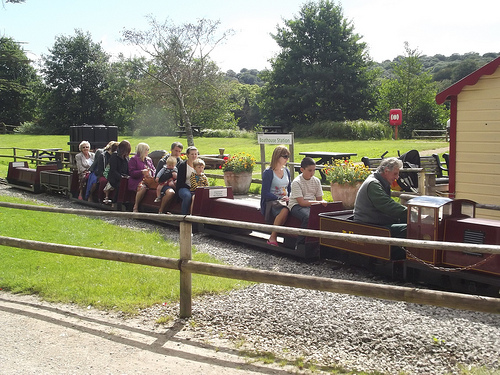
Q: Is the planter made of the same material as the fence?
A: No, the planter is made of concrete and the fence is made of wood.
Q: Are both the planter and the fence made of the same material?
A: No, the planter is made of concrete and the fence is made of wood.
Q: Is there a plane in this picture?
A: No, there are no airplanes.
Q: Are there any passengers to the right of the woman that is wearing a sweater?
A: Yes, there are passengers to the right of the woman.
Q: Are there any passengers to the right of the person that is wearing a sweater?
A: Yes, there are passengers to the right of the woman.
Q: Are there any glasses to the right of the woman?
A: No, there are passengers to the right of the woman.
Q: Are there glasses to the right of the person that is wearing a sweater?
A: No, there are passengers to the right of the woman.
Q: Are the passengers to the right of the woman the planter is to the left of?
A: Yes, the passengers are to the right of the woman.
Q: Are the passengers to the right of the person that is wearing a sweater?
A: Yes, the passengers are to the right of the woman.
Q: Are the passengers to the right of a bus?
A: No, the passengers are to the right of the woman.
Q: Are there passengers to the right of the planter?
A: Yes, there are passengers to the right of the planter.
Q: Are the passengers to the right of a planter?
A: Yes, the passengers are to the right of a planter.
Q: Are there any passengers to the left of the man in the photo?
A: Yes, there are passengers to the left of the man.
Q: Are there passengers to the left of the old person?
A: Yes, there are passengers to the left of the man.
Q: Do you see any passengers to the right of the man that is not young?
A: No, the passengers are to the left of the man.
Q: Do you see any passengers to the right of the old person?
A: No, the passengers are to the left of the man.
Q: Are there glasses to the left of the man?
A: No, there are passengers to the left of the man.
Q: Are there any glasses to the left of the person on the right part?
A: No, there are passengers to the left of the man.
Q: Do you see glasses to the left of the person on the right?
A: No, there are passengers to the left of the man.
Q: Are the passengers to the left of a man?
A: Yes, the passengers are to the left of a man.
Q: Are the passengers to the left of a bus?
A: No, the passengers are to the left of a man.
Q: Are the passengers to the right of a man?
A: No, the passengers are to the left of a man.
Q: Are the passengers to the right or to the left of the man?
A: The passengers are to the left of the man.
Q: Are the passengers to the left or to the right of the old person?
A: The passengers are to the left of the man.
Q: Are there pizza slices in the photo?
A: No, there are no pizza slices.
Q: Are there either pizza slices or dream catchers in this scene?
A: No, there are no pizza slices or dream catchers.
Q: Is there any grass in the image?
A: Yes, there is grass.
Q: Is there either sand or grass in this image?
A: Yes, there is grass.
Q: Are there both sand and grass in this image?
A: No, there is grass but no sand.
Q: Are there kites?
A: No, there are no kites.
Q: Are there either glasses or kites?
A: No, there are no kites or glasses.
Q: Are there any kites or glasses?
A: No, there are no kites or glasses.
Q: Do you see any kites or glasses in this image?
A: No, there are no kites or glasses.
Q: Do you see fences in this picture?
A: Yes, there is a fence.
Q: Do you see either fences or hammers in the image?
A: Yes, there is a fence.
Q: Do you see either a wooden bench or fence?
A: Yes, there is a wood fence.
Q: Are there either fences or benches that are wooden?
A: Yes, the fence is wooden.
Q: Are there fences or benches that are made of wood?
A: Yes, the fence is made of wood.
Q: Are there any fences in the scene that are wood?
A: Yes, there is a wood fence.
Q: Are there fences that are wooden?
A: Yes, there is a fence that is wooden.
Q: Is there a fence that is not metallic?
A: Yes, there is a wooden fence.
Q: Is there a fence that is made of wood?
A: Yes, there is a fence that is made of wood.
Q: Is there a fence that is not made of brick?
A: Yes, there is a fence that is made of wood.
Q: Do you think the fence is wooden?
A: Yes, the fence is wooden.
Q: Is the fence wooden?
A: Yes, the fence is wooden.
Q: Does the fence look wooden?
A: Yes, the fence is wooden.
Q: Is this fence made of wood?
A: Yes, the fence is made of wood.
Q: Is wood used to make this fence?
A: Yes, the fence is made of wood.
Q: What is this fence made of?
A: The fence is made of wood.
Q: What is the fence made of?
A: The fence is made of wood.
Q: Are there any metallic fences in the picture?
A: No, there is a fence but it is wooden.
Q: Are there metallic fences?
A: No, there is a fence but it is wooden.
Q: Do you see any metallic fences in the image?
A: No, there is a fence but it is wooden.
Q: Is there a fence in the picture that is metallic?
A: No, there is a fence but it is wooden.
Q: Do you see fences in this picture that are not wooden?
A: No, there is a fence but it is wooden.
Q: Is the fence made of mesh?
A: No, the fence is made of wood.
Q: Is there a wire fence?
A: No, there is a fence but it is made of wood.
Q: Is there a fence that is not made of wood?
A: No, there is a fence but it is made of wood.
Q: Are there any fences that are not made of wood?
A: No, there is a fence but it is made of wood.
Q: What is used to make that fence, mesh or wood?
A: The fence is made of wood.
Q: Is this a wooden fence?
A: Yes, this is a wooden fence.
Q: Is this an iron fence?
A: No, this is a wooden fence.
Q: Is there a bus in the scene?
A: No, there are no buses.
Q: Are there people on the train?
A: Yes, there are people on the train.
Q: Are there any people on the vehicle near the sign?
A: Yes, there are people on the train.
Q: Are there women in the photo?
A: Yes, there is a woman.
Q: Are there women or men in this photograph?
A: Yes, there is a woman.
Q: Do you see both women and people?
A: Yes, there are both a woman and a person.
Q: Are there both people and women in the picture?
A: Yes, there are both a woman and a person.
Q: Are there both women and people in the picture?
A: Yes, there are both a woman and a person.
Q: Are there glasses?
A: No, there are no glasses.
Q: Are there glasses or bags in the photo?
A: No, there are no glasses or bags.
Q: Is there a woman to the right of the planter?
A: Yes, there is a woman to the right of the planter.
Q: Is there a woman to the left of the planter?
A: No, the woman is to the right of the planter.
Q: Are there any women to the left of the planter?
A: No, the woman is to the right of the planter.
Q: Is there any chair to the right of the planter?
A: No, there is a woman to the right of the planter.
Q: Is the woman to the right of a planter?
A: Yes, the woman is to the right of a planter.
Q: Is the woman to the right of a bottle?
A: No, the woman is to the right of a planter.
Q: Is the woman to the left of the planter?
A: No, the woman is to the right of the planter.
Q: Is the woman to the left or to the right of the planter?
A: The woman is to the right of the planter.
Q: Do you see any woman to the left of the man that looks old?
A: Yes, there is a woman to the left of the man.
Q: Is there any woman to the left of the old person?
A: Yes, there is a woman to the left of the man.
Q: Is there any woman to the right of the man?
A: No, the woman is to the left of the man.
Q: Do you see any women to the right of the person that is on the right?
A: No, the woman is to the left of the man.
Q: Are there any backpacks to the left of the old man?
A: No, there is a woman to the left of the man.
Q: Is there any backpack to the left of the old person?
A: No, there is a woman to the left of the man.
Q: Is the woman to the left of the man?
A: Yes, the woman is to the left of the man.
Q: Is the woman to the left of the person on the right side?
A: Yes, the woman is to the left of the man.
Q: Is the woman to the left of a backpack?
A: No, the woman is to the left of the man.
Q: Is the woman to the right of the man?
A: No, the woman is to the left of the man.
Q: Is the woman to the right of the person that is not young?
A: No, the woman is to the left of the man.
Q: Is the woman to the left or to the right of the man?
A: The woman is to the left of the man.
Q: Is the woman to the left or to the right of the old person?
A: The woman is to the left of the man.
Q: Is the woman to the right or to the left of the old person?
A: The woman is to the left of the man.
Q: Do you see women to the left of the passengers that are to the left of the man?
A: Yes, there is a woman to the left of the passengers.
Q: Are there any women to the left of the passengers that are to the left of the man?
A: Yes, there is a woman to the left of the passengers.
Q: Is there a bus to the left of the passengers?
A: No, there is a woman to the left of the passengers.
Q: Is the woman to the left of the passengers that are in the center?
A: Yes, the woman is to the left of the passengers.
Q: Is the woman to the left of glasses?
A: No, the woman is to the left of the passengers.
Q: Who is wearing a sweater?
A: The woman is wearing a sweater.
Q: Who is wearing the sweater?
A: The woman is wearing a sweater.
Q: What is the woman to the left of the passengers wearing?
A: The woman is wearing a sweater.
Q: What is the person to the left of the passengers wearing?
A: The woman is wearing a sweater.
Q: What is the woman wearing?
A: The woman is wearing a sweater.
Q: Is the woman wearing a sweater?
A: Yes, the woman is wearing a sweater.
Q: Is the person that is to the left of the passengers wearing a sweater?
A: Yes, the woman is wearing a sweater.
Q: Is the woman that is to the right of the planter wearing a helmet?
A: No, the woman is wearing a sweater.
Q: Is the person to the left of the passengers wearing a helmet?
A: No, the woman is wearing a sweater.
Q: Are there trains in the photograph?
A: Yes, there is a train.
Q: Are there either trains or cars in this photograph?
A: Yes, there is a train.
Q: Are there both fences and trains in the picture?
A: Yes, there are both a train and a fence.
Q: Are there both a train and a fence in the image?
A: Yes, there are both a train and a fence.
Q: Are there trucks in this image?
A: No, there are no trucks.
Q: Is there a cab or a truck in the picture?
A: No, there are no trucks or taxis.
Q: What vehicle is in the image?
A: The vehicle is a train.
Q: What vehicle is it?
A: The vehicle is a train.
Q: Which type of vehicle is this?
A: This is a train.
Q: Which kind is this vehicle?
A: This is a train.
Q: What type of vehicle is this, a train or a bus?
A: This is a train.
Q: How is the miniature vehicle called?
A: The vehicle is a train.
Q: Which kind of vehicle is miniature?
A: The vehicle is a train.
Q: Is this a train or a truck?
A: This is a train.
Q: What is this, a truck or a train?
A: This is a train.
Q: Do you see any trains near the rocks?
A: Yes, there is a train near the rocks.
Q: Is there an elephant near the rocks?
A: No, there is a train near the rocks.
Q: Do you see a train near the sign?
A: Yes, there is a train near the sign.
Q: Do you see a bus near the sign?
A: No, there is a train near the sign.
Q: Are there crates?
A: No, there are no crates.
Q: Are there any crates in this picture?
A: No, there are no crates.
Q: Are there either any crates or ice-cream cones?
A: No, there are no crates or ice-cream cones.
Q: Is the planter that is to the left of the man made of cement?
A: Yes, the planter is made of cement.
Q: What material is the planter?
A: The planter is made of cement.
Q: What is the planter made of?
A: The planter is made of concrete.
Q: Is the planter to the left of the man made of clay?
A: No, the planter is made of cement.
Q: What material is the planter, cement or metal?
A: The planter is made of cement.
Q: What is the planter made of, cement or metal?
A: The planter is made of cement.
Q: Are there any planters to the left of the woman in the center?
A: Yes, there is a planter to the left of the woman.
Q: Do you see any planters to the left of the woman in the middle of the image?
A: Yes, there is a planter to the left of the woman.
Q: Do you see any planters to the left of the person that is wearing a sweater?
A: Yes, there is a planter to the left of the woman.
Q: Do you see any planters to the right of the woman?
A: No, the planter is to the left of the woman.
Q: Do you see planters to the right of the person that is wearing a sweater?
A: No, the planter is to the left of the woman.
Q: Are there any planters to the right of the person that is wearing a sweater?
A: No, the planter is to the left of the woman.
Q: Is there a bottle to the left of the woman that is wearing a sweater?
A: No, there is a planter to the left of the woman.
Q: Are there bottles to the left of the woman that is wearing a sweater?
A: No, there is a planter to the left of the woman.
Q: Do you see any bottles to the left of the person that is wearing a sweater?
A: No, there is a planter to the left of the woman.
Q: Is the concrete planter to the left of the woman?
A: Yes, the planter is to the left of the woman.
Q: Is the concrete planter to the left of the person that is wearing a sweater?
A: Yes, the planter is to the left of the woman.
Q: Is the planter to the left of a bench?
A: No, the planter is to the left of the woman.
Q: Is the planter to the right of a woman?
A: No, the planter is to the left of a woman.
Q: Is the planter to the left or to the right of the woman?
A: The planter is to the left of the woman.